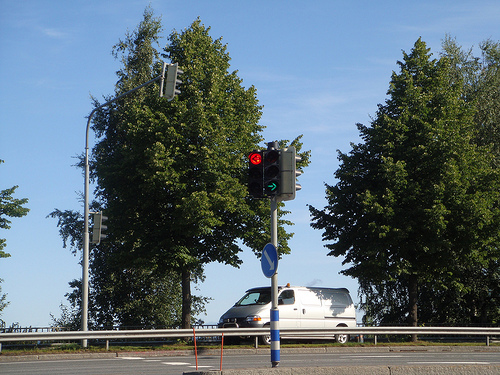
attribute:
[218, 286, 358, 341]
van — white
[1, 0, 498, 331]
blue sky — clear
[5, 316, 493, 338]
barrier — metal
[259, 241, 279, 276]
sign — blue, white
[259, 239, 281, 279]
sign — blue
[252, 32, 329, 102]
sky — clear, blue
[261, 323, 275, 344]
tire — black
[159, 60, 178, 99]
traffic light — metal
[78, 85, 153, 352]
pole — tall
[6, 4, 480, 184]
sky — blue, clear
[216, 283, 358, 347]
van — white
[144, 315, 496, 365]
lines — white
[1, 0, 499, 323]
sky — light-blue, clear, blue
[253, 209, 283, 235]
pole — grey, blue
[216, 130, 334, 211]
light — red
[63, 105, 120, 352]
pole — silver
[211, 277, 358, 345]
van — gray, white, parked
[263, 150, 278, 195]
light — green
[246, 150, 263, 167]
traffic light — red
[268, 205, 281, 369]
pole — traffic light support, blue and white portion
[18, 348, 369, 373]
ashphalt — black patch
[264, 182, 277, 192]
arrow — green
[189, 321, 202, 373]
stick — orange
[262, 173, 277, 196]
arrow — green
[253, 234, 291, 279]
arrow — white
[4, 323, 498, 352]
rail — gray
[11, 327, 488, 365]
street — side of